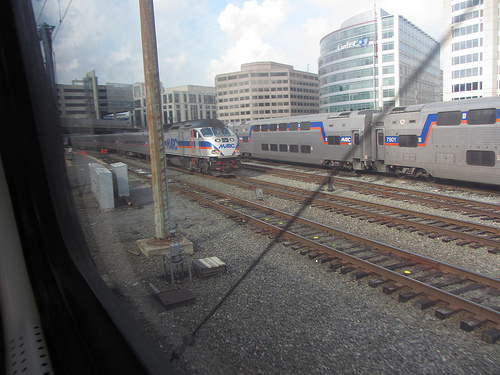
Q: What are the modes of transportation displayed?
A: Trains.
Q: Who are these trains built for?
A: Humans.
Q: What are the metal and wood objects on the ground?
A: Train tracks.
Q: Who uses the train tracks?
A: Trains.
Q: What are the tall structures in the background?
A: Buildings.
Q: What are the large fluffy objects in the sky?
A: Clouds.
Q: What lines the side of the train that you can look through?
A: Windows.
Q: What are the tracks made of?
A: Steel.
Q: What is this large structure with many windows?
A: Building.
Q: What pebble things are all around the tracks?
A: Gravel.